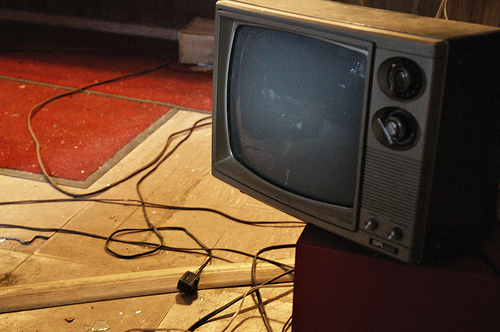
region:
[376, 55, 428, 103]
A dial on the tv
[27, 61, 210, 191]
The brown cord is on the mat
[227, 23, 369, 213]
The monitor of the tv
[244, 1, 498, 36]
The top of the tv is dusty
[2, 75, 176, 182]
The mat is red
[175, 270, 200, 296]
The plug to the cord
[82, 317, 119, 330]
Broken glass on the floor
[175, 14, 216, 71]
Cardboard box on the shelf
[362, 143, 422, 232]
Speaker on the tv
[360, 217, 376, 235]
Little dial on the tv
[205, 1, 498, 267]
Old dirty silver television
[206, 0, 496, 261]
Small metal television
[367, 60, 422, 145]
Two television dials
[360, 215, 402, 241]
Two silver knobs on a television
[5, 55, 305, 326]
Power cords all over the floor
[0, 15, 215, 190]
Two red floor carpets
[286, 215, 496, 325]
Burgundy cube shaped table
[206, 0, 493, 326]
Television balancing on a table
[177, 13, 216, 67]
Sealed white box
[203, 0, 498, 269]
Old gray television with knobs and dials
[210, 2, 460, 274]
TV on a red box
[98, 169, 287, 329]
Electric cord on the floor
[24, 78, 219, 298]
Electric cord on the floor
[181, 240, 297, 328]
Electric cord on the floor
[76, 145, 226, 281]
Electric cord on the floor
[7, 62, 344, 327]
black cords on the floor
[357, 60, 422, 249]
black knobs on the tv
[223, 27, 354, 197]
screen of the tv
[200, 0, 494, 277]
black standard definition tv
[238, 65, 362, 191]
reflection on the tv screen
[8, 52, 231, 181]
red rugs on the floor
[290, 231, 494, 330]
plum colored stand tv is on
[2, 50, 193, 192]
gray trim on red rugs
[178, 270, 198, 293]
plug of the cord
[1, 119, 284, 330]
light colored wood flooring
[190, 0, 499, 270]
television on wooden table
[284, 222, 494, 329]
wooden table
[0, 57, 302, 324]
brown wires on floor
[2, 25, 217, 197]
red rug on floor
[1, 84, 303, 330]
hardwood floors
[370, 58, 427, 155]
knobs on front of television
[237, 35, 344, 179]
reflection in tv glass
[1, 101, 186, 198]
black liner on red rug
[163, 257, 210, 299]
end of brown power cord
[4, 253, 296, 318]
elevated brown woode panel on floor